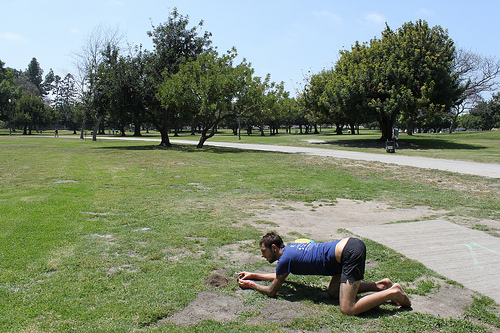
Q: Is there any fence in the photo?
A: No, there are no fences.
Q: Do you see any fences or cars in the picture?
A: No, there are no fences or cars.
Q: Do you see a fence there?
A: No, there are no fences.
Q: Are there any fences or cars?
A: No, there are no fences or cars.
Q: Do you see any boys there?
A: No, there are no boys.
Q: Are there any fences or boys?
A: No, there are no boys or fences.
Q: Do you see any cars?
A: No, there are no cars.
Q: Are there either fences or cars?
A: No, there are no cars or fences.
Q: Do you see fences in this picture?
A: No, there are no fences.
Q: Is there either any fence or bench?
A: No, there are no fences or benches.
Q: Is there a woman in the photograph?
A: No, there are no women.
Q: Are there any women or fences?
A: No, there are no women or fences.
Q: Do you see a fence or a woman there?
A: No, there are no women or fences.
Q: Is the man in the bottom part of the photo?
A: Yes, the man is in the bottom of the image.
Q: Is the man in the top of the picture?
A: No, the man is in the bottom of the image.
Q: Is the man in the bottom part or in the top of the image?
A: The man is in the bottom of the image.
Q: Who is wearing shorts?
A: The man is wearing shorts.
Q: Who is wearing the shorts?
A: The man is wearing shorts.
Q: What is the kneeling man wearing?
A: The man is wearing shorts.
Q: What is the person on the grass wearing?
A: The man is wearing shorts.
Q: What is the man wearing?
A: The man is wearing shorts.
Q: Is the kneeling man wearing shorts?
A: Yes, the man is wearing shorts.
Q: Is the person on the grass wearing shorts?
A: Yes, the man is wearing shorts.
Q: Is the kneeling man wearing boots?
A: No, the man is wearing shorts.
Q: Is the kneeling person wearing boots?
A: No, the man is wearing shorts.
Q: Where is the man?
A: The man is on the grass.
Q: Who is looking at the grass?
A: The man is looking at the grass.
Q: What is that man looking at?
A: The man is looking at the grass.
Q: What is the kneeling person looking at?
A: The man is looking at the grass.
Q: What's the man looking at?
A: The man is looking at the grass.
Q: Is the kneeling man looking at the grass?
A: Yes, the man is looking at the grass.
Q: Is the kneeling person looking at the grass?
A: Yes, the man is looking at the grass.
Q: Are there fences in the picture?
A: No, there are no fences.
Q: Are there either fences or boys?
A: No, there are no fences or boys.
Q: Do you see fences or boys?
A: No, there are no fences or boys.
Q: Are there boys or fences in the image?
A: No, there are no fences or boys.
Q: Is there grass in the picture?
A: Yes, there is grass.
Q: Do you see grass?
A: Yes, there is grass.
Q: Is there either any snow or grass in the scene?
A: Yes, there is grass.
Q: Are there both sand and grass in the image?
A: No, there is grass but no sand.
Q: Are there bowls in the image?
A: No, there are no bowls.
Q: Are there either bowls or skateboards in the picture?
A: No, there are no bowls or skateboards.